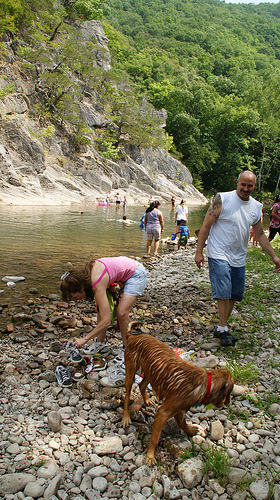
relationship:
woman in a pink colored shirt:
[58, 255, 148, 348] [93, 258, 140, 282]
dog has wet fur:
[123, 314, 239, 471] [142, 352, 184, 387]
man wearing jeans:
[198, 163, 277, 337] [204, 256, 253, 307]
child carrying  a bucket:
[171, 218, 192, 247] [170, 231, 176, 243]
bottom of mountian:
[10, 177, 202, 206] [4, 2, 279, 179]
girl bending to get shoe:
[58, 255, 148, 348] [64, 341, 83, 364]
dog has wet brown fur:
[123, 314, 239, 471] [142, 352, 184, 387]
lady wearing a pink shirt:
[58, 255, 148, 348] [93, 258, 140, 282]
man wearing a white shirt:
[198, 163, 277, 337] [212, 191, 259, 265]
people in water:
[89, 182, 193, 248] [5, 207, 193, 299]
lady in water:
[142, 196, 163, 263] [5, 207, 193, 299]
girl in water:
[173, 200, 189, 232] [5, 207, 193, 299]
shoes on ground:
[54, 343, 112, 392] [0, 237, 274, 497]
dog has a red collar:
[123, 314, 239, 471] [200, 365, 216, 408]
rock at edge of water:
[6, 337, 143, 499] [5, 207, 193, 299]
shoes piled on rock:
[54, 343, 112, 392] [6, 337, 143, 499]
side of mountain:
[5, 35, 196, 208] [4, 2, 279, 179]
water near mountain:
[5, 207, 193, 299] [4, 2, 279, 179]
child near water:
[171, 218, 192, 247] [5, 207, 193, 299]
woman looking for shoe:
[58, 255, 148, 348] [64, 341, 83, 364]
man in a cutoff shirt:
[198, 163, 277, 337] [212, 191, 259, 265]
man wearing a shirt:
[198, 163, 277, 337] [212, 191, 259, 265]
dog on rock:
[123, 314, 239, 471] [6, 337, 143, 499]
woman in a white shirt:
[173, 200, 189, 232] [173, 202, 194, 221]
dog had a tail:
[123, 314, 239, 471] [122, 315, 150, 338]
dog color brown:
[123, 314, 239, 471] [155, 350, 178, 391]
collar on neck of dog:
[200, 365, 216, 408] [123, 314, 239, 471]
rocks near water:
[10, 177, 202, 206] [5, 207, 193, 299]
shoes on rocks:
[54, 343, 112, 392] [0, 237, 274, 497]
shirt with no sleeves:
[212, 191, 259, 265] [214, 193, 222, 216]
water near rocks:
[5, 207, 193, 299] [0, 237, 274, 497]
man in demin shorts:
[198, 163, 277, 337] [204, 256, 253, 307]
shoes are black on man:
[214, 327, 241, 346] [198, 163, 277, 337]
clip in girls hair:
[61, 265, 75, 288] [61, 261, 96, 299]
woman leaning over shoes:
[58, 255, 148, 348] [54, 343, 112, 392]